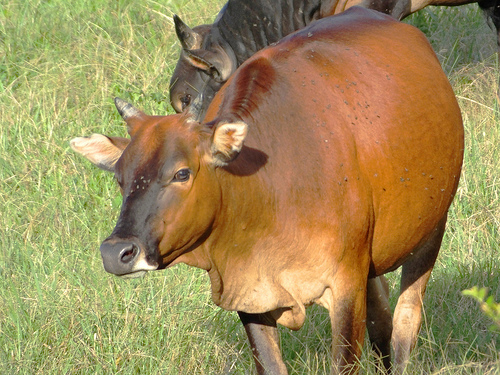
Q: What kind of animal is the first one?
A: Cow.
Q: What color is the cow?
A: Brown.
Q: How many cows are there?
A: 1.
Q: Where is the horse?
A: Behind the cow.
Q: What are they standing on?
A: Grass.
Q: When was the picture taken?
A: Daytime.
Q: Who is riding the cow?
A: Nobody.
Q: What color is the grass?
A: Green.